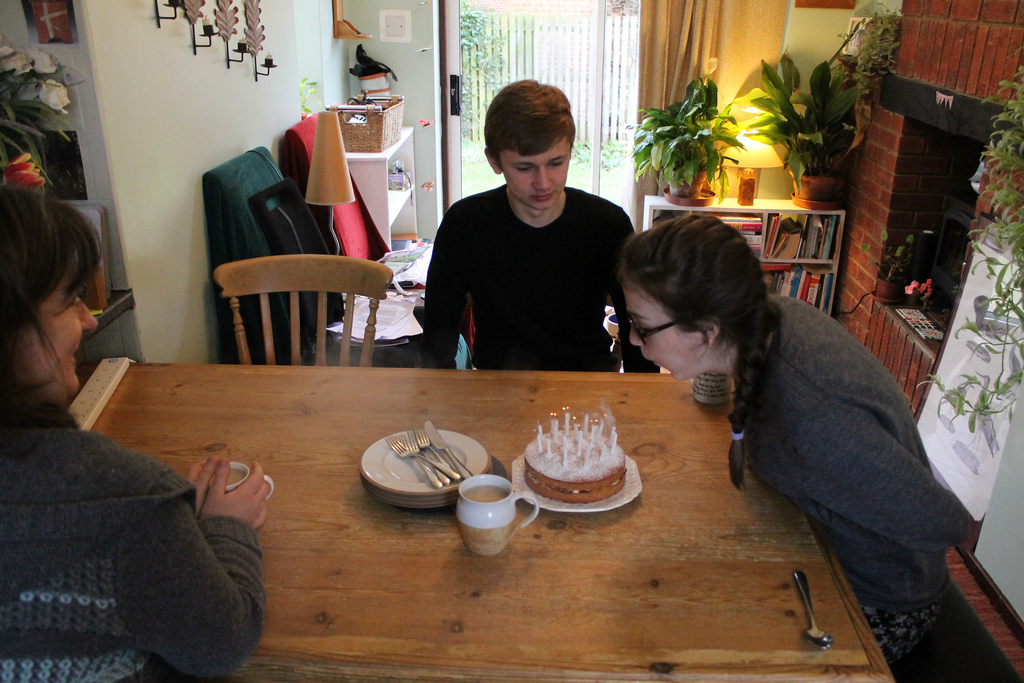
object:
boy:
[424, 79, 663, 372]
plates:
[359, 427, 494, 507]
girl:
[621, 215, 975, 666]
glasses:
[625, 311, 688, 346]